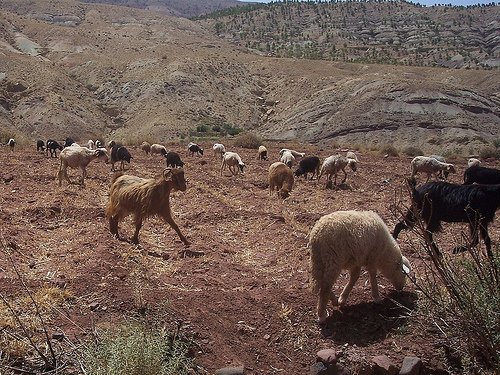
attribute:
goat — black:
[164, 148, 185, 170]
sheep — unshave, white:
[3, 129, 494, 316]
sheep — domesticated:
[299, 201, 418, 326]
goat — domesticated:
[94, 157, 190, 249]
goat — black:
[386, 163, 498, 263]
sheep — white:
[265, 186, 446, 341]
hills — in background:
[0, 0, 498, 146]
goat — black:
[108, 142, 138, 170]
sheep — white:
[219, 150, 248, 177]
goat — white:
[306, 209, 408, 302]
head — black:
[231, 158, 252, 174]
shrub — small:
[83, 307, 188, 372]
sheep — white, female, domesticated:
[309, 209, 411, 321]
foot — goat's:
[153, 210, 204, 258]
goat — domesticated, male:
[81, 170, 207, 245]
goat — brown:
[100, 161, 192, 244]